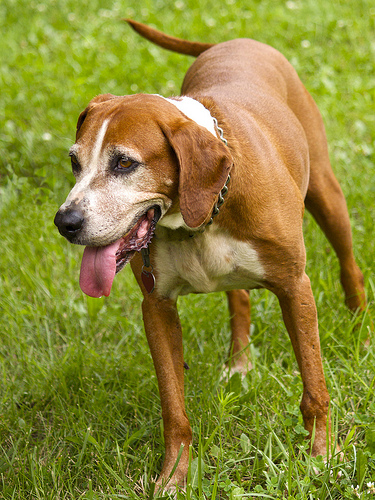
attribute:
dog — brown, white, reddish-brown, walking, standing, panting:
[48, 14, 367, 498]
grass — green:
[4, 8, 373, 494]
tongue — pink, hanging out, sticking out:
[77, 247, 119, 300]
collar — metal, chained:
[132, 97, 235, 294]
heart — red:
[139, 269, 160, 296]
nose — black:
[53, 208, 84, 240]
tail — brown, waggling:
[119, 14, 214, 62]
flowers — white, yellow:
[332, 469, 374, 499]